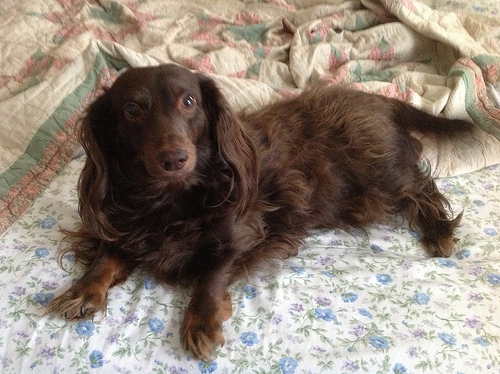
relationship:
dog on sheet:
[72, 48, 474, 325] [258, 274, 489, 371]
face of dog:
[93, 67, 211, 184] [72, 48, 474, 325]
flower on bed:
[312, 304, 337, 325] [3, 7, 499, 369]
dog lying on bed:
[72, 48, 474, 325] [10, 288, 493, 371]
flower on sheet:
[88, 348, 101, 369] [258, 274, 489, 371]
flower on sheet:
[241, 331, 257, 347] [258, 274, 489, 371]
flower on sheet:
[279, 351, 299, 372] [258, 274, 489, 371]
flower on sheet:
[312, 304, 337, 325] [258, 274, 489, 371]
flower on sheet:
[367, 333, 389, 350] [258, 274, 489, 371]